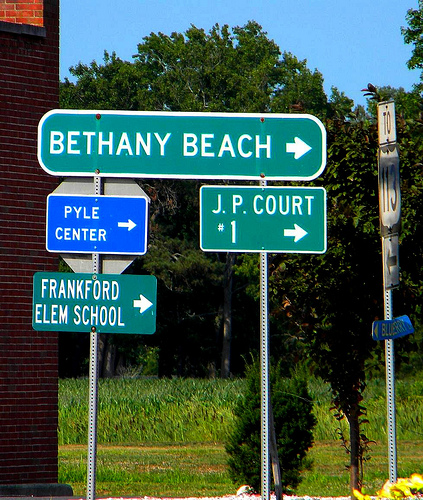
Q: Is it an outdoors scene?
A: Yes, it is outdoors.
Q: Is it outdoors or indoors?
A: It is outdoors.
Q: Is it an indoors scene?
A: No, it is outdoors.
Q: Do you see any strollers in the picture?
A: No, there are no strollers.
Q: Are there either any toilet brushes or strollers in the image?
A: No, there are no strollers or toilet brushes.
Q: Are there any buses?
A: No, there are no buses.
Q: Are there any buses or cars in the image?
A: No, there are no buses or cars.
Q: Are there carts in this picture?
A: No, there are no carts.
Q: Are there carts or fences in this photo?
A: No, there are no carts or fences.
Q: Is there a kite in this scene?
A: No, there are no kites.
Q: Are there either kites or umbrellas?
A: No, there are no kites or umbrellas.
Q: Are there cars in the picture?
A: No, there are no cars.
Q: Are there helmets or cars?
A: No, there are no cars or helmets.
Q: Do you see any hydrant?
A: No, there are no fire hydrants.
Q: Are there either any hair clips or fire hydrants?
A: No, there are no fire hydrants or hair clips.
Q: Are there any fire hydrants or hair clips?
A: No, there are no fire hydrants or hair clips.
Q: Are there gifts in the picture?
A: No, there are no gifts.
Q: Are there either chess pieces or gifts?
A: No, there are no gifts or chess pieces.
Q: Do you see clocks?
A: No, there are no clocks.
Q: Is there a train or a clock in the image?
A: No, there are no clocks or trains.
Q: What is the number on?
A: The number is on the sign.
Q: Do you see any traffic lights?
A: No, there are no traffic lights.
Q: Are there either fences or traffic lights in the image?
A: No, there are no traffic lights or fences.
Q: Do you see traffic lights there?
A: No, there are no traffic lights.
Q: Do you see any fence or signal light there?
A: No, there are no traffic lights or fences.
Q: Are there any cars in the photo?
A: No, there are no cars.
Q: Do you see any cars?
A: No, there are no cars.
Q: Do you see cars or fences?
A: No, there are no cars or fences.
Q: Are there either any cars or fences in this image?
A: No, there are no cars or fences.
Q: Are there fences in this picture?
A: No, there are no fences.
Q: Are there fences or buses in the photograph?
A: No, there are no fences or buses.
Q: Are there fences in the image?
A: No, there are no fences.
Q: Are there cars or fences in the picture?
A: No, there are no fences or cars.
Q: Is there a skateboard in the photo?
A: No, there are no skateboards.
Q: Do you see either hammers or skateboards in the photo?
A: No, there are no skateboards or hammers.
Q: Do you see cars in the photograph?
A: No, there are no cars.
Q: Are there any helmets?
A: No, there are no helmets.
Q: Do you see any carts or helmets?
A: No, there are no helmets or carts.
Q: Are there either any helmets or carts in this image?
A: No, there are no helmets or carts.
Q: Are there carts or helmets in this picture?
A: No, there are no helmets or carts.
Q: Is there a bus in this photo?
A: No, there are no buses.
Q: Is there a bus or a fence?
A: No, there are no buses or fences.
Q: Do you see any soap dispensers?
A: No, there are no soap dispensers.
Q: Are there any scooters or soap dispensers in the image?
A: No, there are no soap dispensers or scooters.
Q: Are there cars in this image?
A: No, there are no cars.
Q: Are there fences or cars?
A: No, there are no cars or fences.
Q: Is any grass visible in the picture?
A: Yes, there is grass.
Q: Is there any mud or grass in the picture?
A: Yes, there is grass.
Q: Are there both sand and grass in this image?
A: No, there is grass but no sand.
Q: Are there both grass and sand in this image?
A: No, there is grass but no sand.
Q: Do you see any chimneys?
A: No, there are no chimneys.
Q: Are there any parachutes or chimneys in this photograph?
A: No, there are no chimneys or parachutes.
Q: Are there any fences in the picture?
A: No, there are no fences.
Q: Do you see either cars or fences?
A: No, there are no fences or cars.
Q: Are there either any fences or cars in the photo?
A: No, there are no fences or cars.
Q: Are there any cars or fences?
A: No, there are no fences or cars.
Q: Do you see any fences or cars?
A: No, there are no fences or cars.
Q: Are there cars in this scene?
A: No, there are no cars.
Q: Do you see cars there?
A: No, there are no cars.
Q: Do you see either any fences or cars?
A: No, there are no cars or fences.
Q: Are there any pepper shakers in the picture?
A: No, there are no pepper shakers.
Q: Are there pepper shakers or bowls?
A: No, there are no pepper shakers or bowls.